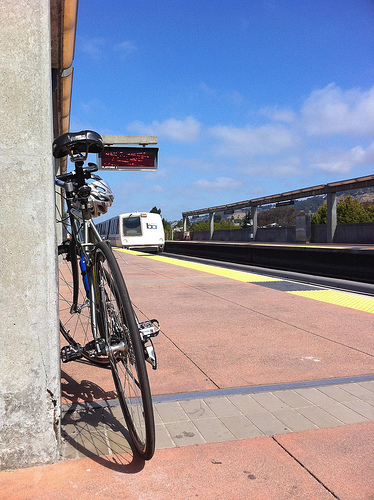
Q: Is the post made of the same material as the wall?
A: Yes, both the post and the wall are made of cement.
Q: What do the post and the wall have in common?
A: The material, both the post and the wall are concrete.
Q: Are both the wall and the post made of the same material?
A: Yes, both the wall and the post are made of cement.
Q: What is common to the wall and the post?
A: The material, both the wall and the post are concrete.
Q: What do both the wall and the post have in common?
A: The material, both the wall and the post are concrete.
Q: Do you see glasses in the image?
A: No, there are no glasses.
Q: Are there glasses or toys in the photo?
A: No, there are no glasses or toys.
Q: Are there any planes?
A: No, there are no planes.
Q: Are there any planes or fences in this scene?
A: No, there are no planes or fences.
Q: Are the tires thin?
A: Yes, the tires are thin.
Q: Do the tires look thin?
A: Yes, the tires are thin.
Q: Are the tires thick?
A: No, the tires are thin.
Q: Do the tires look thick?
A: No, the tires are thin.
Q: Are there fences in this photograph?
A: No, there are no fences.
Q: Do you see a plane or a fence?
A: No, there are no fences or airplanes.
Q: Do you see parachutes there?
A: No, there are no parachutes.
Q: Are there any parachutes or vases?
A: No, there are no parachutes or vases.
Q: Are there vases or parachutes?
A: No, there are no parachutes or vases.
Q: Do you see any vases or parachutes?
A: No, there are no parachutes or vases.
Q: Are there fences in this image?
A: No, there are no fences.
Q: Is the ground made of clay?
A: No, the ground is made of stone.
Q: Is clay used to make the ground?
A: No, the ground is made of stone.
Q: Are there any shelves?
A: No, there are no shelves.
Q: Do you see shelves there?
A: No, there are no shelves.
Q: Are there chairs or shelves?
A: No, there are no shelves or chairs.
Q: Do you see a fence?
A: No, there are no fences.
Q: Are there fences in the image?
A: No, there are no fences.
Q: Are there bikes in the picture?
A: Yes, there is a bike.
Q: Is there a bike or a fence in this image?
A: Yes, there is a bike.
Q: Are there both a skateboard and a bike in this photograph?
A: No, there is a bike but no skateboards.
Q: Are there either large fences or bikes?
A: Yes, there is a large bike.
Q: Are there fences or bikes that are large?
A: Yes, the bike is large.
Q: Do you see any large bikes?
A: Yes, there is a large bike.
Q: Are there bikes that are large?
A: Yes, there is a bike that is large.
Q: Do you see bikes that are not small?
A: Yes, there is a large bike.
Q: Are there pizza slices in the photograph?
A: No, there are no pizza slices.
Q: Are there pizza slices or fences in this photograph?
A: No, there are no pizza slices or fences.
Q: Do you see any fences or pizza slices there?
A: No, there are no pizza slices or fences.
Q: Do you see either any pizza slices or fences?
A: No, there are no pizza slices or fences.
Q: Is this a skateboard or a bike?
A: This is a bike.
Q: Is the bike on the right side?
A: No, the bike is on the left of the image.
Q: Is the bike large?
A: Yes, the bike is large.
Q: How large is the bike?
A: The bike is large.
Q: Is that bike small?
A: No, the bike is large.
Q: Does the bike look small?
A: No, the bike is large.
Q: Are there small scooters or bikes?
A: No, there is a bike but it is large.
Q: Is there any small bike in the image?
A: No, there is a bike but it is large.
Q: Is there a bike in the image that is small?
A: No, there is a bike but it is large.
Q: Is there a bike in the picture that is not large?
A: No, there is a bike but it is large.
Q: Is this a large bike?
A: Yes, this is a large bike.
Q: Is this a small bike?
A: No, this is a large bike.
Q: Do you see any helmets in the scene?
A: Yes, there is a helmet.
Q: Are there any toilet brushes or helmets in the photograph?
A: Yes, there is a helmet.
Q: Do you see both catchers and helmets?
A: No, there is a helmet but no catchers.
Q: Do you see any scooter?
A: No, there are no scooters.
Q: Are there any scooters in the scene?
A: No, there are no scooters.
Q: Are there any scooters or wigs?
A: No, there are no scooters or wigs.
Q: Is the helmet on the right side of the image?
A: No, the helmet is on the left of the image.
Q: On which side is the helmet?
A: The helmet is on the left of the image.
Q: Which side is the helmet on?
A: The helmet is on the left of the image.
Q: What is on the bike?
A: The helmet is on the bike.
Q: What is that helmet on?
A: The helmet is on the bike.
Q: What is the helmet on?
A: The helmet is on the bike.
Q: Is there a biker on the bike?
A: No, there is a helmet on the bike.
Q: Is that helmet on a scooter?
A: No, the helmet is on the bike.